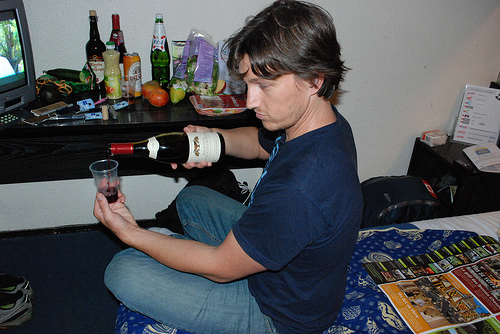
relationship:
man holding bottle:
[85, 3, 358, 333] [105, 129, 226, 163]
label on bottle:
[184, 127, 222, 166] [105, 129, 226, 163]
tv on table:
[0, 0, 44, 116] [0, 68, 319, 181]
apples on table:
[137, 82, 170, 106] [0, 68, 319, 181]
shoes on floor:
[0, 270, 34, 327] [6, 210, 125, 331]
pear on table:
[169, 83, 185, 104] [0, 68, 319, 181]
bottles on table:
[83, 9, 175, 100] [0, 68, 319, 181]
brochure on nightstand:
[460, 137, 500, 170] [407, 132, 499, 219]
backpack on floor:
[354, 165, 445, 225] [6, 210, 125, 331]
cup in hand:
[91, 157, 118, 201] [86, 191, 144, 239]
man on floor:
[85, 3, 358, 333] [6, 210, 125, 331]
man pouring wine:
[85, 3, 358, 333] [97, 154, 120, 204]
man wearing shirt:
[85, 3, 358, 333] [230, 122, 360, 332]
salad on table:
[174, 40, 225, 99] [0, 68, 319, 181]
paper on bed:
[361, 231, 499, 334] [115, 201, 499, 333]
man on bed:
[85, 3, 358, 333] [115, 201, 499, 333]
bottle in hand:
[105, 129, 226, 163] [86, 191, 144, 239]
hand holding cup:
[86, 191, 144, 239] [91, 157, 118, 201]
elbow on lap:
[168, 235, 249, 288] [165, 191, 260, 334]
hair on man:
[222, 2, 350, 99] [85, 3, 358, 333]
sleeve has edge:
[232, 175, 327, 276] [230, 218, 283, 272]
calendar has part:
[361, 231, 499, 334] [399, 236, 400, 237]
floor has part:
[6, 210, 125, 331] [399, 236, 400, 237]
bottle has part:
[105, 129, 226, 163] [399, 236, 400, 237]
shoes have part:
[0, 270, 34, 327] [399, 236, 400, 237]